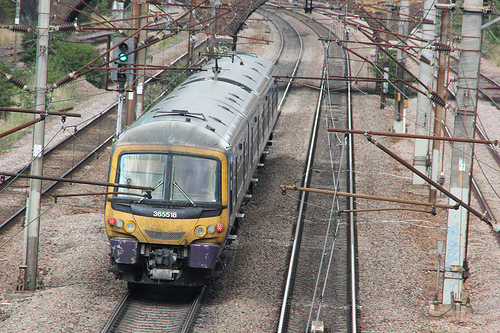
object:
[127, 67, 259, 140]
train roof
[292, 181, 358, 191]
tracks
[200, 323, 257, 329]
ground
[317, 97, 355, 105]
track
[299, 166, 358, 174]
tracks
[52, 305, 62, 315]
gravel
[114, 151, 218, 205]
front windshield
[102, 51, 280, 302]
passenger train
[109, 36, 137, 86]
traffic signal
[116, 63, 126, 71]
light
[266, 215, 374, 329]
railroad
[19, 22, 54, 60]
powerlines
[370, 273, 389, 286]
ground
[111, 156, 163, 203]
windshield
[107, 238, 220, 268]
bumper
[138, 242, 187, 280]
coupling device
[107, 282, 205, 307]
railroad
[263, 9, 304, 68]
railroad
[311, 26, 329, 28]
train tracks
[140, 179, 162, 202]
wiper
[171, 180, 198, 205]
wiper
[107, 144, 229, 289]
front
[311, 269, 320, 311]
wires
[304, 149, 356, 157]
track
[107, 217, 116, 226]
headlight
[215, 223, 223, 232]
headlight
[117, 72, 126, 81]
light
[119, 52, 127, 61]
green light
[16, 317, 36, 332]
ground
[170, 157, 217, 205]
shield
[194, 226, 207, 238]
head lights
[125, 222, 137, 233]
head lights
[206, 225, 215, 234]
head lights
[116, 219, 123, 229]
head lights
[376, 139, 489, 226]
poles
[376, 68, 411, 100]
power lines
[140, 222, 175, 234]
yellow part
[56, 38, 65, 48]
shrubs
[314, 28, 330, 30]
train track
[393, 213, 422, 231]
ground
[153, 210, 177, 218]
identification number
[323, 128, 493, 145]
poles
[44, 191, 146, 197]
poles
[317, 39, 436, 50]
poles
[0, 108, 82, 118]
poles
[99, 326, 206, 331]
track